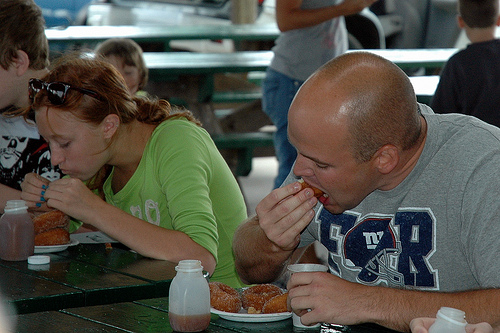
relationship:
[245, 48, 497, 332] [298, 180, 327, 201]
man eating a doughnut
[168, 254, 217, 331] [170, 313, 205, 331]
jug of juice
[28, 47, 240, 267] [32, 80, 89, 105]
woman has sunglasses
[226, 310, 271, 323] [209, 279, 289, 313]
plate of donuts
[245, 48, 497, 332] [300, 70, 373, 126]
man with bald head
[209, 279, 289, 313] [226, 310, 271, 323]
three doughnuts on a plate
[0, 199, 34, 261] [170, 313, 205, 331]
bottle has juice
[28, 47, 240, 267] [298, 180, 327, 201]
woman eating a doughnut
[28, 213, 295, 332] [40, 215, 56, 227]
food have sugar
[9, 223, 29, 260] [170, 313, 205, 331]
bottle of juice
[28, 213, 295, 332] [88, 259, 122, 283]
food on table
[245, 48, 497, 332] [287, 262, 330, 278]
man has a cup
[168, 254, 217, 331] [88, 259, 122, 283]
jug on table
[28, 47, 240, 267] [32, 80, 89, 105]
woman wearing sunglasses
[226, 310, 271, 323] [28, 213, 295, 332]
plate has food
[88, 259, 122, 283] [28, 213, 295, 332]
table with food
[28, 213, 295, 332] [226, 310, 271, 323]
food on a plate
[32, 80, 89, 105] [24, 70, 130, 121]
sunglasses on head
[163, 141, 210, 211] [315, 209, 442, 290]
shirt with a logo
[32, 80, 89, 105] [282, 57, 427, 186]
glasses on head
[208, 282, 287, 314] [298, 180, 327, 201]
donuts in mouth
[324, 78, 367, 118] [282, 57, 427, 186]
shine on head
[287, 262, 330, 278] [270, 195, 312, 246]
cup in hand